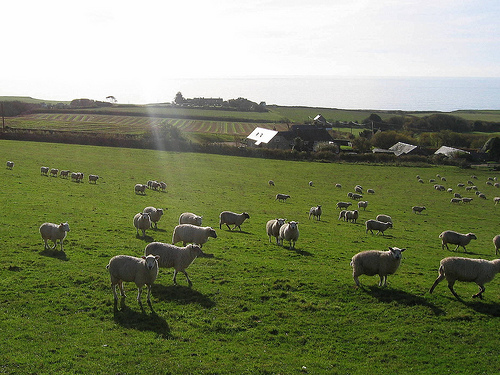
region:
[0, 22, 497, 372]
Sheep in a green pasture.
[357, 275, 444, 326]
The shadow of a sheep.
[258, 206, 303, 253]
Two sheep standing next to each other.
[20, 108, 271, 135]
A field in the distance.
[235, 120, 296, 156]
A building in the distance.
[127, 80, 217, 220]
A ray of sunlight shining down.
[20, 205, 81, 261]
A little baby sheep.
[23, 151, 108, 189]
The sheep are walking in a line.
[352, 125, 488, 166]
More buildings in the distance.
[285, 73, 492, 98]
The sky is light blue.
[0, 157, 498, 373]
a herd of sheep on farmland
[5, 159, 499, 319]
sheep in a field covered with green grass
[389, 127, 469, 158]
the roofs of farmland structures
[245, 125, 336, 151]
a country style house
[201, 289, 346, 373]
green grass on the farmland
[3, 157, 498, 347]
a flock of sheep in a natural habitat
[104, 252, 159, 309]
a sheep watching the owner of the property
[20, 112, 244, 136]
a field containing planted crop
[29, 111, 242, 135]
a crop field on the other of the farm house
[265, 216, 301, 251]
two sheep looking at the cameraman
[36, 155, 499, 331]
Sheep in a field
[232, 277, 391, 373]
Green grass besides animals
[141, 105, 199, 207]
Sunlight streaming onto field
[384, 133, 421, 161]
House in background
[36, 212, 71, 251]
Sheep all by itself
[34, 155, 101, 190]
Line of five sheep in background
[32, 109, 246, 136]
Cultivated field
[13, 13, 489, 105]
Sky is bright and clear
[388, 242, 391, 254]
Sheep's ear is black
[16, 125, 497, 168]
Shrubbery on border of field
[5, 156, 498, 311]
a field of white sheep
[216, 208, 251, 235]
a sheep running down the hill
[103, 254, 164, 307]
a sheep looking at the camera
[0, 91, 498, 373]
a vast green field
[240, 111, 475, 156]
a group of houses in the background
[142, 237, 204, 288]
a white sheep walking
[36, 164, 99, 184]
a group of sheep in a line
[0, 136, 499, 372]
a green grassy hill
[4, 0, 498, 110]
a bright cloudy sky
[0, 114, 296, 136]
a plowed field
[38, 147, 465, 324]
sheep in the field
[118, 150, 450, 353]
the field of grass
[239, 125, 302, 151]
the house in the distance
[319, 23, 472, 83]
the sky is blue and clear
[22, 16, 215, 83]
the sun is shining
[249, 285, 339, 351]
the grass is green and trimmed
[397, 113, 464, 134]
the trees with green leaves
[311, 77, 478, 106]
the water is calm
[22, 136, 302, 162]
the hedge row at the edge of the field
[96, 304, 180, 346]
the shadow on the ground